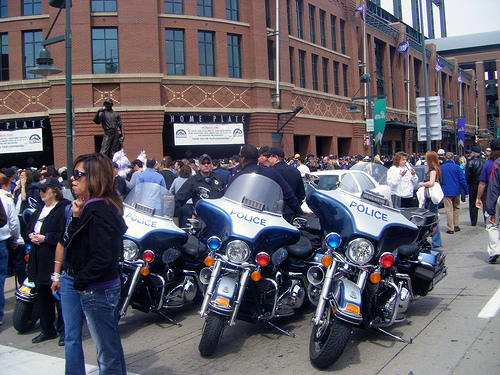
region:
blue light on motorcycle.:
[208, 235, 219, 248]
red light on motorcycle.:
[253, 252, 272, 268]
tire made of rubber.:
[201, 318, 223, 343]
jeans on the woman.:
[100, 315, 109, 351]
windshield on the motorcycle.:
[245, 178, 265, 189]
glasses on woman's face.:
[71, 167, 82, 177]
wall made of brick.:
[130, 40, 142, 58]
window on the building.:
[93, 35, 111, 52]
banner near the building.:
[375, 100, 385, 130]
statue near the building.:
[103, 104, 118, 134]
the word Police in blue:
[349, 201, 390, 223]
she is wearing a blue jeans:
[84, 287, 129, 373]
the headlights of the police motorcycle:
[331, 232, 393, 266]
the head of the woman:
[71, 158, 118, 205]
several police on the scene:
[128, 165, 446, 365]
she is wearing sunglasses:
[71, 170, 90, 180]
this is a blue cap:
[31, 175, 61, 188]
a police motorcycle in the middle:
[196, 175, 310, 350]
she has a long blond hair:
[425, 152, 442, 177]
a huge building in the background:
[3, 4, 463, 136]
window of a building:
[18, 28, 50, 78]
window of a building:
[90, 0, 109, 16]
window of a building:
[102, 2, 122, 22]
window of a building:
[91, 20, 123, 75]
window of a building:
[159, 2, 182, 11]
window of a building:
[196, 0, 215, 22]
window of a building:
[223, 6, 238, 23]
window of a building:
[230, 30, 247, 47]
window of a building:
[224, 45, 244, 70]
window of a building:
[192, 30, 219, 82]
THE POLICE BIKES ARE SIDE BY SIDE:
[7, 147, 453, 367]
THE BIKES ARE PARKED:
[11, 141, 446, 366]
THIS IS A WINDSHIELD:
[220, 166, 300, 221]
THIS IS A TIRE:
[187, 310, 233, 365]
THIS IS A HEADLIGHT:
[341, 232, 381, 272]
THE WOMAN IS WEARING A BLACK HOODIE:
[57, 195, 132, 286]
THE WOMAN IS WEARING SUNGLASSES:
[62, 165, 94, 180]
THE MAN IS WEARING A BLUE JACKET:
[433, 155, 468, 200]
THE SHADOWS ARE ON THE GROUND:
[10, 243, 497, 373]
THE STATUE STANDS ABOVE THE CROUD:
[85, 93, 130, 162]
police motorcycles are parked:
[109, 160, 466, 373]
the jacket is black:
[66, 206, 132, 285]